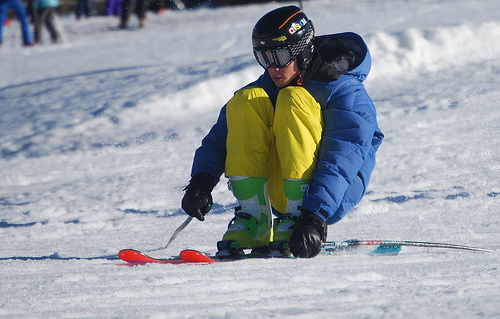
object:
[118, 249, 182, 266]
ski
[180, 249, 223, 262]
ski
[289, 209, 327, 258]
glove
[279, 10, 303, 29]
stripe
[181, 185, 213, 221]
hand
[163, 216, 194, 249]
pole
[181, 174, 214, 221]
glove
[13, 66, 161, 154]
snow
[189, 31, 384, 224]
jacket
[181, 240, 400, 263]
board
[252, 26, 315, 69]
glasses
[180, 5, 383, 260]
man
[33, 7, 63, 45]
pants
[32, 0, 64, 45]
man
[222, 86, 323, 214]
pants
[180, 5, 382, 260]
girl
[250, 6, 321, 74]
helment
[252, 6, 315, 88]
head